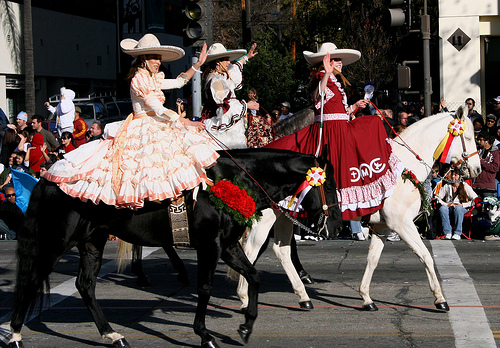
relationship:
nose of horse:
[467, 161, 485, 178] [228, 102, 495, 322]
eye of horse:
[464, 135, 471, 141] [227, 103, 481, 309]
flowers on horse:
[207, 178, 260, 228] [5, 142, 344, 346]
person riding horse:
[116, 40, 212, 205] [21, 116, 380, 346]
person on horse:
[116, 40, 212, 205] [5, 142, 344, 346]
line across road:
[425, 239, 497, 345] [1, 222, 497, 346]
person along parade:
[429, 168, 481, 241] [1, 30, 485, 252]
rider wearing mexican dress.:
[313, 42, 373, 227] [256, 69, 403, 221]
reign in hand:
[202, 127, 292, 216] [170, 113, 187, 127]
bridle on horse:
[436, 116, 475, 170] [21, 116, 380, 346]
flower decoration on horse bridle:
[303, 163, 331, 191] [290, 178, 315, 205]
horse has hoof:
[5, 142, 344, 346] [7, 340, 23, 346]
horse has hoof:
[5, 142, 344, 346] [111, 337, 128, 346]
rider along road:
[306, 41, 381, 223] [0, 222, 500, 347]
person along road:
[116, 45, 202, 179] [0, 222, 500, 347]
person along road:
[429, 168, 479, 240] [0, 222, 500, 347]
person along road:
[28, 105, 55, 176] [0, 222, 500, 347]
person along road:
[31, 114, 62, 153] [0, 222, 500, 347]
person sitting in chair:
[429, 168, 481, 241] [431, 173, 481, 241]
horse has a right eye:
[21, 116, 380, 346] [325, 177, 335, 192]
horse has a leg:
[227, 103, 481, 309] [357, 222, 387, 304]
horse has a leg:
[227, 103, 481, 309] [394, 220, 449, 302]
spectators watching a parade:
[4, 87, 499, 250] [2, 36, 484, 345]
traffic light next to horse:
[180, 1, 210, 48] [227, 103, 481, 309]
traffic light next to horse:
[180, 1, 210, 48] [5, 142, 344, 346]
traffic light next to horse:
[180, 1, 210, 48] [118, 103, 315, 286]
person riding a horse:
[116, 40, 212, 205] [202, 140, 346, 345]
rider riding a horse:
[306, 41, 381, 223] [360, 105, 479, 312]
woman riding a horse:
[202, 42, 263, 149] [118, 103, 315, 286]